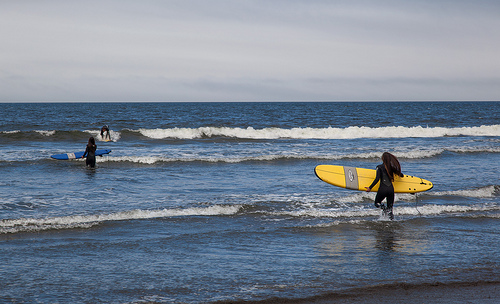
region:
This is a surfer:
[238, 125, 483, 216]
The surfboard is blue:
[53, 133, 94, 179]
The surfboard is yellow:
[277, 168, 414, 213]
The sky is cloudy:
[154, 41, 324, 147]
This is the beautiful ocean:
[107, 112, 284, 244]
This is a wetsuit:
[59, 144, 137, 192]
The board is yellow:
[353, 158, 400, 219]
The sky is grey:
[265, 36, 315, 88]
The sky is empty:
[90, 38, 207, 125]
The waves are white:
[132, 114, 234, 178]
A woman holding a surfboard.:
[311, 137, 434, 229]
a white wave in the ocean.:
[0, 113, 499, 148]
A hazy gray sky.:
[0, 2, 499, 106]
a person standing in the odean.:
[72, 130, 109, 182]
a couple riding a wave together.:
[95, 118, 118, 146]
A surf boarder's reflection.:
[320, 227, 442, 266]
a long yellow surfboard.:
[307, 163, 452, 191]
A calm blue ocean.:
[2, 102, 498, 125]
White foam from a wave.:
[57, 148, 166, 177]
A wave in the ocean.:
[0, 185, 340, 242]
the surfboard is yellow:
[300, 149, 488, 204]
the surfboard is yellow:
[296, 167, 469, 219]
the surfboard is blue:
[35, 134, 113, 166]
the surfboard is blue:
[12, 125, 147, 171]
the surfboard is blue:
[57, 143, 147, 182]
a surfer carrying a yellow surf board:
[308, 151, 440, 209]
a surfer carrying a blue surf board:
[56, 129, 111, 174]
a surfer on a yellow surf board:
[96, 117, 119, 146]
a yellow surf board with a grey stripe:
[311, 157, 436, 199]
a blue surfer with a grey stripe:
[45, 146, 118, 161]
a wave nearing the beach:
[0, 115, 499, 138]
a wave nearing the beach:
[4, 146, 499, 167]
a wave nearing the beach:
[1, 185, 499, 220]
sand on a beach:
[259, 277, 495, 302]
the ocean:
[41, 102, 436, 119]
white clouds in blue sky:
[9, 0, 30, 40]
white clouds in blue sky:
[77, 21, 127, 79]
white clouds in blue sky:
[187, 40, 215, 64]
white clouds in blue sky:
[260, 27, 317, 79]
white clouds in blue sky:
[354, 39, 394, 93]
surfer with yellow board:
[297, 136, 448, 224]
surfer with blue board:
[77, 134, 111, 181]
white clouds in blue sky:
[234, 10, 261, 52]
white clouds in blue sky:
[350, 21, 387, 69]